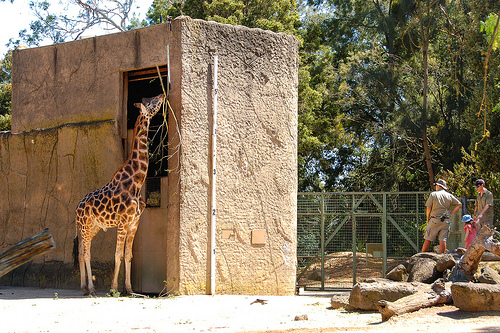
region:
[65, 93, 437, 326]
Enclosed habitat home giraffe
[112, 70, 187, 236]
Opening holds food dispenser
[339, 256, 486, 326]
Logs add habitat appearance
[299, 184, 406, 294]
Chain link fence outer barrier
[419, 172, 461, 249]
Zoo keeper inspects area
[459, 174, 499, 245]
Man daughter visit compound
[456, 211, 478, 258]
Small child ponytail red clothes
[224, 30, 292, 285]
Side building interesting facade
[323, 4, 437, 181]
Wooded area outside compound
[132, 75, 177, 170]
Tall neck gets food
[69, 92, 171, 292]
the giraffe is eating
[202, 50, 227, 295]
a tall white pole beside the building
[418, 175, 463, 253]
a man has his hand on his hip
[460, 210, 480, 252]
a child wearing a blue hat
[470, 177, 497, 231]
a man is wearing a blue visor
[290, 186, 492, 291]
the metal fence is green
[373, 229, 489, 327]
the fallen log is brown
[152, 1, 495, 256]
trees in the background are green and leafy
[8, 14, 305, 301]
the small building is tan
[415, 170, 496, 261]
three people are standing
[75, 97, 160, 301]
a giraffe eating food off a branch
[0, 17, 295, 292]
the building next to the giraffe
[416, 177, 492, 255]
people standing by each other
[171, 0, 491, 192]
a group of tall trees next to the fence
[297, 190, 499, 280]
a metal fence next to the people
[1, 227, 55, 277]
a piece of wood next to the giraffe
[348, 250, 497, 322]
more wood on the ground in a pile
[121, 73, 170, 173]
a window of the building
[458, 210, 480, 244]
a little girl wearing a blue hat and pink dress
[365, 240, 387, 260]
a sign by the fence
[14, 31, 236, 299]
baby giraffe eating branches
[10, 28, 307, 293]
small clay adobe style building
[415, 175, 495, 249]
two zookeepers standing observing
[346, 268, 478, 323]
wood log on the ground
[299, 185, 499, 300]
fence around giraffe enclosure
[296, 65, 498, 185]
many trees behind the fence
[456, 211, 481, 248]
girl with pink shirt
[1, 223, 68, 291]
log behind the giraffe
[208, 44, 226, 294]
measuring tape attached to the wall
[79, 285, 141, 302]
giraffe has black hooves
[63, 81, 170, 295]
Tall Giraffe reaching for branch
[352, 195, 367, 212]
Hole in Fence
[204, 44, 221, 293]
marked measuring stick shows how tall giraffe is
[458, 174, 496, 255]
Little Girl is holding an adult's hand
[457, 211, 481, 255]
Little Girl is wearing a Pink dress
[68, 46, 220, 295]
The Giraffe is not 6 feet tall yet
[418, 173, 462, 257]
The Park ranger has a black gun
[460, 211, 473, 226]
The Little Girl is wearing a Blue Hat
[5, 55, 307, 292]
Giraffe is standing in the shade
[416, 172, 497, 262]
Three People in this picture